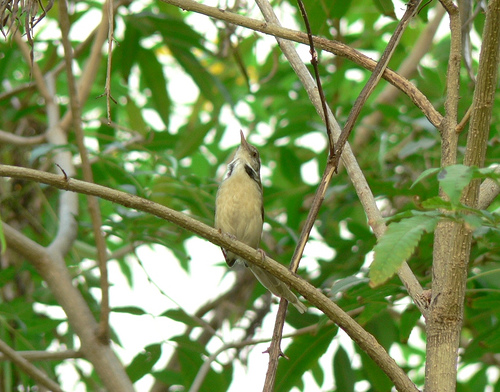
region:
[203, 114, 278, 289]
White and black bird on limb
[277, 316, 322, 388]
Bright green leaf in a tree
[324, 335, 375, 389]
Bright green leaf in a tree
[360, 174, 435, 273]
Bright green leaf in a tree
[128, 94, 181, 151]
Bright green leaf in a tree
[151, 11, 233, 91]
Bright green leaf in a tree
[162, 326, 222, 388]
Bright green leaf in a tree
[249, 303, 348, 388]
Bright green leaf in a tree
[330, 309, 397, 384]
Bright green leaf in a tree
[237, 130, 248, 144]
The beak of the bird.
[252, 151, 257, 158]
The eye of the bird.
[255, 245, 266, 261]
The right foot of the bird.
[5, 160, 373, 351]
The branch the bird is perched on.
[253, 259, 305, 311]
The tail feathers of the bird.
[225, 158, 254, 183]
The black markings on the bird's feathers.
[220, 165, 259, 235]
The chest area of the bird.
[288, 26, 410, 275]
The dark brown branch to the right of the bird.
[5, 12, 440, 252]
The green leaves behind the bird.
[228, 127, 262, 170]
The head of the bird.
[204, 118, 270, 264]
a finch sitting on a branch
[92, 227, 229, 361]
green leaves on a tree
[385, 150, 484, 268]
green leaves on a tree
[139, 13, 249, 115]
green leaves on a tree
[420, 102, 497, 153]
brown branches on a tree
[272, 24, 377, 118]
brown branches on a tree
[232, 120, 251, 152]
the finches pointed beak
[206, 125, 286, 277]
finch looking up in the air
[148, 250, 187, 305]
the sky through the leaves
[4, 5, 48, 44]
brown branches on a tree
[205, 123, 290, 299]
bird sitting on a branch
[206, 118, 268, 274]
bird looking upwards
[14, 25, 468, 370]
tree with many small branches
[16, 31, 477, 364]
tree with many green leaves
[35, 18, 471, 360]
only one bird sitting on a tree branch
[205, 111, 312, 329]
bird with yellow feathers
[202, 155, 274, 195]
black feathers near birds neck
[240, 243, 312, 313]
birds tail hanging below tree branch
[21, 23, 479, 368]
sky can be seen through leaves and branches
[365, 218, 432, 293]
green leaf starting to turn yellow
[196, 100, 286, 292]
little bird looking upwards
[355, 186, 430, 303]
leaf on a big tree branch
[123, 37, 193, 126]
green leaf in a tree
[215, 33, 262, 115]
green leaf in a tree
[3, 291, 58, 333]
green leaf in a tree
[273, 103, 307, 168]
green leaf in a tree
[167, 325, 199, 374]
green leaf in a tree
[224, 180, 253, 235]
yellow belly on a bird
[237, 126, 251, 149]
little beak on a bird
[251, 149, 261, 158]
black eye on a bird